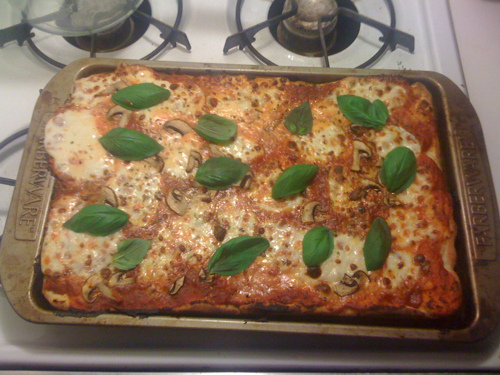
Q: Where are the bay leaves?
A: Top of pizza.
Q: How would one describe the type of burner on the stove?
A: Gas.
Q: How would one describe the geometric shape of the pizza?
A: Rectangular.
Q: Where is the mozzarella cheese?
A: Top of pizza.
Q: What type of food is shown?
A: Pizza.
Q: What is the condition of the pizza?
A: Cooked and uncut.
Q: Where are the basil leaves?
A: On top of the pizza.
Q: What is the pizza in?
A: Pan.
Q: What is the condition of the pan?
A: Stained.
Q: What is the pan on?
A: Stove.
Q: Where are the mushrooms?
A: On top of the pizza.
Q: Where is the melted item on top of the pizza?
A: Cheese.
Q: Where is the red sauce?
A: On the pizza crust.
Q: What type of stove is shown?
A: Gas stove.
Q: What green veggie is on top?
A: Basil.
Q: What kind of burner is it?
A: Gas.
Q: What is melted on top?
A: Cheese.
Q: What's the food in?
A: Tray.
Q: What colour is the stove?
A: White.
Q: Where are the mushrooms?
A: On top.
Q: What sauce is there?
A: Tomato.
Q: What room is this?
A: Kitchen.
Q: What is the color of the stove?
A: White.